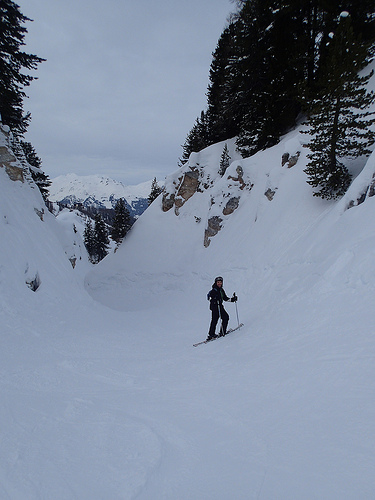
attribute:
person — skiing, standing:
[207, 277, 237, 339]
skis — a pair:
[191, 322, 244, 348]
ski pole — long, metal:
[216, 301, 225, 337]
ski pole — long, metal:
[232, 293, 241, 328]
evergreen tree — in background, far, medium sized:
[109, 198, 137, 243]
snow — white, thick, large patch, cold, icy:
[0, 60, 374, 499]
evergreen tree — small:
[300, 43, 375, 199]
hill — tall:
[86, 54, 374, 312]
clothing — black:
[206, 285, 232, 338]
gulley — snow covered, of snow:
[24, 156, 257, 360]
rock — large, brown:
[161, 169, 199, 213]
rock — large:
[204, 162, 244, 250]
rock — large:
[280, 150, 300, 168]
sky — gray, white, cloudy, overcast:
[13, 1, 243, 187]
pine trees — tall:
[179, 1, 374, 168]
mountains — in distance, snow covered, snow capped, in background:
[46, 172, 168, 213]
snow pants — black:
[209, 305, 229, 335]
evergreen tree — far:
[93, 210, 111, 260]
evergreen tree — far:
[84, 219, 95, 254]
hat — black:
[213, 277, 223, 284]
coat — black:
[207, 284, 233, 309]